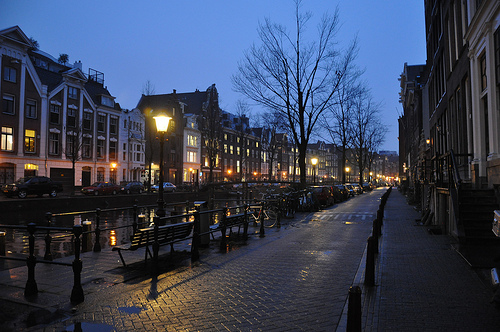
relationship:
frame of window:
[467, 20, 498, 165] [474, 45, 492, 159]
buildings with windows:
[168, 20, 397, 191] [186, 132, 288, 167]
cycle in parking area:
[253, 196, 280, 222] [241, 175, 307, 225]